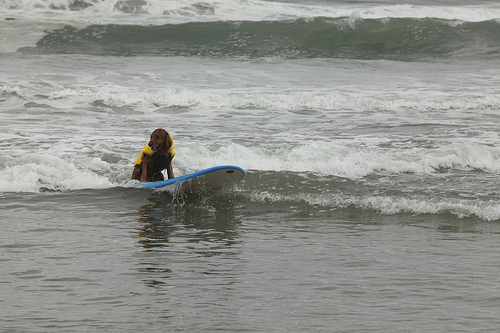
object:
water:
[0, 40, 499, 330]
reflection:
[138, 188, 244, 287]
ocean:
[0, 0, 499, 331]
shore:
[0, 173, 499, 331]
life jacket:
[134, 134, 176, 167]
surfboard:
[142, 165, 245, 193]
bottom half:
[132, 166, 165, 182]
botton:
[141, 165, 245, 193]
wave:
[1, 27, 498, 163]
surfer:
[132, 128, 175, 182]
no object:
[74, 6, 206, 73]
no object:
[252, 77, 395, 137]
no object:
[328, 3, 462, 75]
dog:
[131, 128, 174, 182]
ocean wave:
[15, 16, 500, 62]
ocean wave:
[244, 188, 499, 222]